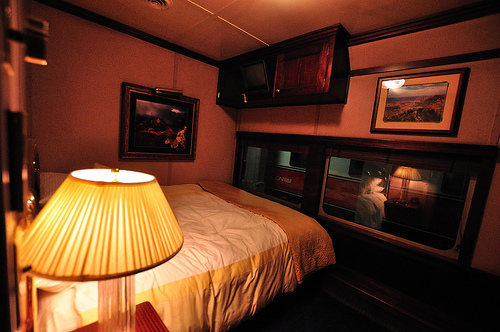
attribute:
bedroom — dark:
[5, 2, 497, 328]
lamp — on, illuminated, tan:
[21, 165, 195, 331]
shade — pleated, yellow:
[22, 167, 181, 282]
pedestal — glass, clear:
[99, 273, 137, 330]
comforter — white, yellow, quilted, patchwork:
[29, 176, 334, 331]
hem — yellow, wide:
[53, 239, 301, 331]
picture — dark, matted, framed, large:
[118, 80, 197, 164]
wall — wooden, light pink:
[22, 2, 235, 186]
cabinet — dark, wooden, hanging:
[214, 24, 349, 105]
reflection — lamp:
[356, 164, 453, 241]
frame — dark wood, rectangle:
[120, 79, 198, 160]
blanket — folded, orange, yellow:
[198, 178, 336, 285]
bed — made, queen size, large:
[15, 139, 335, 329]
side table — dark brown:
[70, 303, 167, 332]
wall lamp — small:
[154, 83, 185, 95]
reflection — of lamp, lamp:
[377, 76, 409, 92]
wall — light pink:
[230, 25, 498, 269]